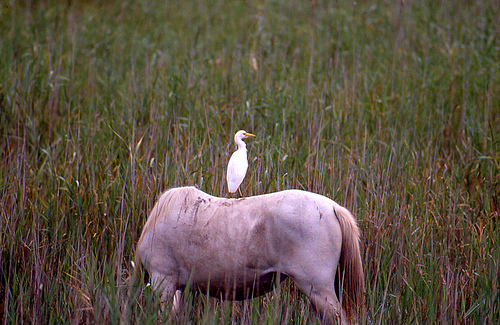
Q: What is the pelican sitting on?
A: Horse.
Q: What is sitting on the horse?
A: Pelican.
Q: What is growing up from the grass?
A: Weeds.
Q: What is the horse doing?
A: Grazing.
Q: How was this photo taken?
A: Very clearly.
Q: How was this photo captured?
A: With a telephoto lens.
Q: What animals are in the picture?
A: A horse and bird.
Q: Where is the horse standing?
A: Field of high grass.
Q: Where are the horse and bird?
A: In a field of tall grass.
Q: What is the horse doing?
A: Grazing.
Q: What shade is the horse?
A: White.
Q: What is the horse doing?
A: Grazing.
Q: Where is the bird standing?
A: On the horse.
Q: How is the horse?
A: Dirty.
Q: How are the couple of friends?
A: Symbiotic.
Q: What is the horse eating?
A: Grass.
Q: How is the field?
A: Grassy.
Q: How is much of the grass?
A: Dry and brown.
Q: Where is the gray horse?
A: In the grass.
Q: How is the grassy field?
A: Green.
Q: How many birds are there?
A: One.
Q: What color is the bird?
A: White.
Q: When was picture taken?
A: Daytime.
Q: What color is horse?
A: Tan.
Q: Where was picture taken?
A: In a zoo.